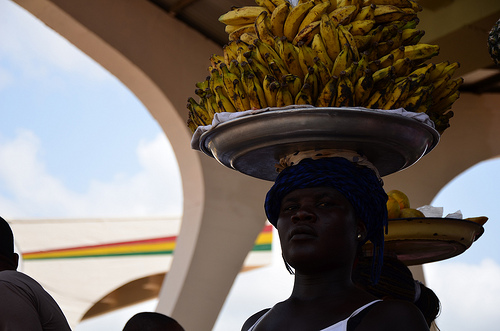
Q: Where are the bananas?
A: On the lady's head.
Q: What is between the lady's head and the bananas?
A: A silver tray.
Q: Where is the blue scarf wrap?
A: On the girl's head.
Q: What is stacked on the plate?
A: A bunch of bananas.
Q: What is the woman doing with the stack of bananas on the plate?
A: Balancing them on her head.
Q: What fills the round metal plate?
A: A stack of bananas.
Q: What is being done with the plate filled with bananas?
A: The woman balances the plate on her head.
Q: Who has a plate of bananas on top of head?
A: A young woman.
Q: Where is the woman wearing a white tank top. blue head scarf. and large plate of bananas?
A: Woman wearing hat.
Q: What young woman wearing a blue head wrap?
A: Woman with long hair.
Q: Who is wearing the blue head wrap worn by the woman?
A: Woman in white top.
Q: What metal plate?
A: On woman head.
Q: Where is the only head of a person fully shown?
A: Woman in background.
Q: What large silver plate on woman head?
A: Woman with bananas.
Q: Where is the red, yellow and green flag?
A: Left of photo.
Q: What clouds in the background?
A: Back of woman.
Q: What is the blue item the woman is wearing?
A: Bandana.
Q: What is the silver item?
A: Tray.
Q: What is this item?
A: Rainbow.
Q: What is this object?
A: Archway.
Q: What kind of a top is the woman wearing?
A: Tank top.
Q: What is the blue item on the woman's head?
A: Headgear.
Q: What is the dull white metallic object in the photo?
A: Tray.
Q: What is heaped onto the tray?
A: Bananas.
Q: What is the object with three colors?
A: Long band.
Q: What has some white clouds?
A: A blue sky.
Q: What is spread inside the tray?
A: A Piece of cloth.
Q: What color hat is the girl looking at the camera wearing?
A: Blue.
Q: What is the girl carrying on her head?
A: Platter.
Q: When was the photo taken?
A: Daytime.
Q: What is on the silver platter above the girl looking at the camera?
A: Bananas.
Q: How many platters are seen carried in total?
A: Two.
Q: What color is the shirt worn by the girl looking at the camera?
A: White.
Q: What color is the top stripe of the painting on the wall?
A: Red.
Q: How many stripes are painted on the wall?
A: Three.